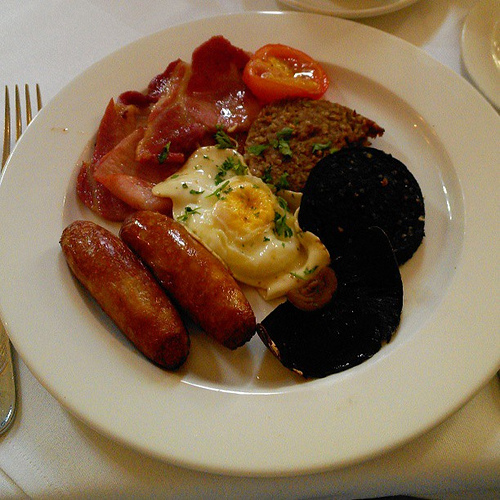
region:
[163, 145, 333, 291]
An egg is in the center.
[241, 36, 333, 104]
A tomato is on the plate.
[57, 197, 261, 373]
Two sausages are on the plate.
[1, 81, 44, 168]
A fork is by the plate.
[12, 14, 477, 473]
The plate is white.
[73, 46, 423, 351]
Breakfast is on the plate.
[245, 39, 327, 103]
The tomato is red.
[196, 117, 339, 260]
Green seasoning is on the food.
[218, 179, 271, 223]
The yolk is yellow.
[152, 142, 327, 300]
The egg is fried.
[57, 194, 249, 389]
two sausages on the plate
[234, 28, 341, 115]
a slice of red tomato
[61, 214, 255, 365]
two pieces of sausage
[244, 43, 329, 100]
a piece of cooked tomato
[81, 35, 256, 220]
slices of ham on the side of the plate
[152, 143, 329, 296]
a fried egg in the center of the plate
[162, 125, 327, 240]
green basil sprinkled on top of the food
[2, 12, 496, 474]
a plate filled with food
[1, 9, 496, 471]
a large, white plate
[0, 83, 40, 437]
a silver fork on the side of the plate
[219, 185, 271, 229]
the yolk of the egg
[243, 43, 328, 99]
tomato is cut if half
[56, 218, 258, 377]
Two sausages on a plate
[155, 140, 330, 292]
A fried egg on a plate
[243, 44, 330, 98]
A tomato on a plate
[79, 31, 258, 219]
Meat on a plate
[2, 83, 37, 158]
Tines on a fork near a plate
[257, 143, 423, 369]
Black food on a plate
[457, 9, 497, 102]
Side of a small white plate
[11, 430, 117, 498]
A tablecloth under a plate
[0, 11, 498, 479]
A white plate under food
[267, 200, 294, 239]
Parsley on an egg on a plate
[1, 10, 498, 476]
the plate is white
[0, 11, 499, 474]
the plate is round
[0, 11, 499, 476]
the food on the plate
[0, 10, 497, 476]
the plate under the food